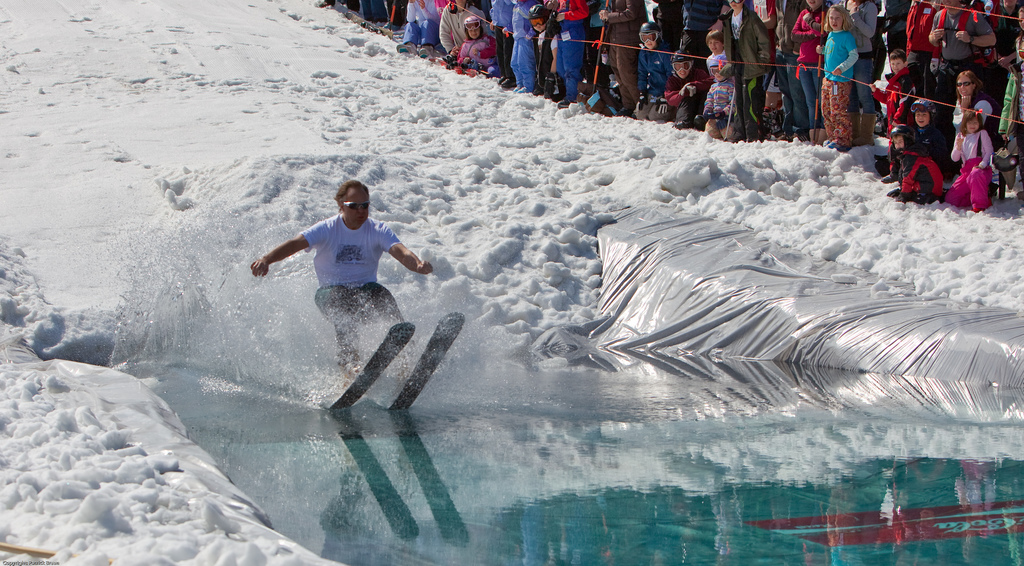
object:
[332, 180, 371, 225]
head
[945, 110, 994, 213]
person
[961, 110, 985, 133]
head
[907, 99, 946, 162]
person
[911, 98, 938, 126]
head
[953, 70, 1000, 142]
person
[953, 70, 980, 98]
head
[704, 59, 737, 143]
person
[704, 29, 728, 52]
head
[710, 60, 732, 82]
head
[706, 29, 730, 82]
person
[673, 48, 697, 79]
head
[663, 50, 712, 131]
person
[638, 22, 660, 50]
head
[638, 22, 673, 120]
person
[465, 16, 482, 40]
head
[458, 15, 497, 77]
person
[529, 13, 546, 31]
head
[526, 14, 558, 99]
person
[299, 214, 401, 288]
shirt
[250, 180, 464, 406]
man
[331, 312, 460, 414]
skis